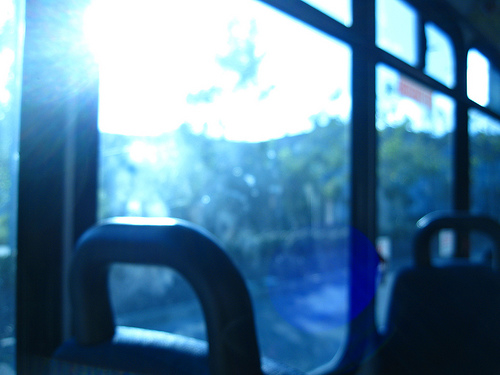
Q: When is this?
A: Daytime.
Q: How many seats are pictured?
A: One.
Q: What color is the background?
A: Blue.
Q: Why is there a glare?
A: It is the sunlight.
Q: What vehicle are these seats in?
A: A bus.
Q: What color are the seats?
A: Black.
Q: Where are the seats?
A: To the right of the window.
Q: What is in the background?
A: The street.